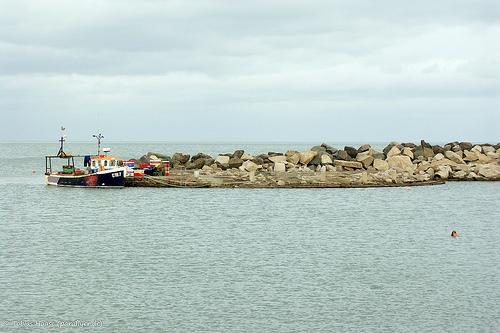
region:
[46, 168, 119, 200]
Black boat in water.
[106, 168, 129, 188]
White letters on side of boat.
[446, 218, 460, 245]
Orange object in water.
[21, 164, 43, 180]
Orange object in water.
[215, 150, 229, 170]
Gray rock on land.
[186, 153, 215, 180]
Brown rock on land.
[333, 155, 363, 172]
Gray rock on land.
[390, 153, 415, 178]
Gray rock on land.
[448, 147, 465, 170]
Gray rock on land.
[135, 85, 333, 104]
White clouds in sky.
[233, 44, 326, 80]
this is the sky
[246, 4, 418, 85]
the sky is blue in color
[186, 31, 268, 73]
these are the clouds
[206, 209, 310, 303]
this is a water body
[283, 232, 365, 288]
the water is calm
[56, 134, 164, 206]
this is a boat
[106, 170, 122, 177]
the boat is black in color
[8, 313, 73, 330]
this is a writing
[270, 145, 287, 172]
this is a rock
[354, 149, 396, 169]
the rock is brown in color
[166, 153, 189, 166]
rock is next to rock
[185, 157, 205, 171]
rock is next to rock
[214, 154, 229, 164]
rock is next to rock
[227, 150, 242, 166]
rock is next to rock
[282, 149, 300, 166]
rock is next to rock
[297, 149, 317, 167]
rock is next to rock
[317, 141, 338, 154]
rock is next to rock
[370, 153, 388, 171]
rock is next to rock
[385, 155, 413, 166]
rock is next to rock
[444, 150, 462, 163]
rock is next to rock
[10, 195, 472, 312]
water on one side of rock island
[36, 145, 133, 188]
boat near rock island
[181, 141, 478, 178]
rocks on an island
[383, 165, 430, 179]
lighter colored rocks on island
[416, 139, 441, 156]
darker colored rocks on island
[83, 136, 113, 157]
structure on the boat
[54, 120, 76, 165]
structure on the boat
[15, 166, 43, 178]
item in the water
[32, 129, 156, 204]
boat in the ocean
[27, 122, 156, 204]
tow boats docked next to one another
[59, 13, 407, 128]
gray cloudy skies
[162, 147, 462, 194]
island made of rocks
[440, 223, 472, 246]
person swimming in the water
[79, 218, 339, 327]
very calm ocean surface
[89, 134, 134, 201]
boat is black and white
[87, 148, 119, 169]
boat has yellow top